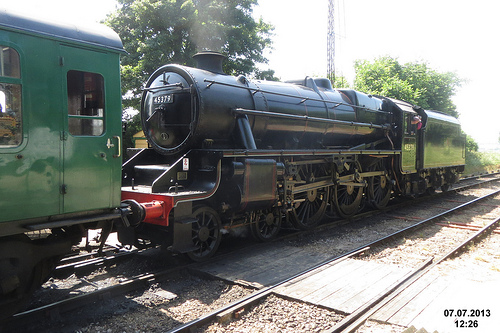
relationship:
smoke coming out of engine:
[190, 0, 227, 55] [137, 54, 391, 158]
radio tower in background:
[327, 0, 339, 90] [1, 0, 496, 166]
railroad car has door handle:
[0, 8, 125, 297] [110, 133, 123, 160]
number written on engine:
[151, 91, 175, 107] [137, 54, 391, 158]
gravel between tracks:
[2, 170, 499, 332] [0, 171, 497, 331]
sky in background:
[2, 0, 500, 114] [1, 0, 496, 166]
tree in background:
[100, 0, 278, 147] [1, 0, 496, 166]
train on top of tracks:
[1, 0, 465, 313] [0, 171, 497, 331]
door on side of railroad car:
[57, 39, 122, 216] [0, 8, 125, 297]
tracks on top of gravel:
[0, 171, 497, 331] [2, 170, 499, 332]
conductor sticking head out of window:
[411, 112, 423, 136] [400, 110, 417, 135]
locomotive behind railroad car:
[120, 51, 468, 263] [0, 8, 125, 297]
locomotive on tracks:
[120, 51, 468, 263] [0, 171, 497, 331]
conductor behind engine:
[411, 112, 423, 136] [137, 54, 391, 158]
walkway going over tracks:
[86, 224, 499, 332] [0, 171, 497, 331]